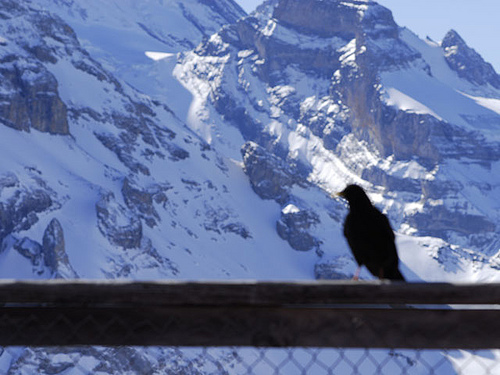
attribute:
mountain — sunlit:
[129, 60, 459, 215]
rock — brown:
[323, 77, 404, 120]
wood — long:
[1, 278, 484, 306]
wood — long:
[1, 304, 484, 349]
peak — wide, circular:
[191, 1, 420, 88]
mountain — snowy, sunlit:
[1, 2, 483, 371]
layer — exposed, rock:
[230, 61, 387, 195]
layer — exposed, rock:
[251, 58, 457, 198]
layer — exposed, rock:
[201, 72, 312, 175]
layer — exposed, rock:
[228, 18, 339, 76]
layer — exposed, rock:
[254, 6, 352, 40]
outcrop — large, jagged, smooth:
[2, 165, 51, 243]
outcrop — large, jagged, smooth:
[40, 215, 78, 277]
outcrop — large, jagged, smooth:
[89, 185, 144, 247]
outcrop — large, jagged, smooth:
[1, 38, 71, 136]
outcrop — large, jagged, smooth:
[119, 173, 163, 228]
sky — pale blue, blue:
[233, 1, 484, 70]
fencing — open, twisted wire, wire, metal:
[0, 299, 484, 371]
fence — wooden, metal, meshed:
[8, 278, 484, 370]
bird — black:
[333, 180, 409, 283]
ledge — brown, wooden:
[1, 271, 481, 361]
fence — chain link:
[6, 350, 483, 373]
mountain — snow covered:
[10, 10, 458, 280]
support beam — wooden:
[13, 302, 483, 347]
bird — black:
[339, 182, 402, 287]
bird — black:
[338, 182, 415, 287]